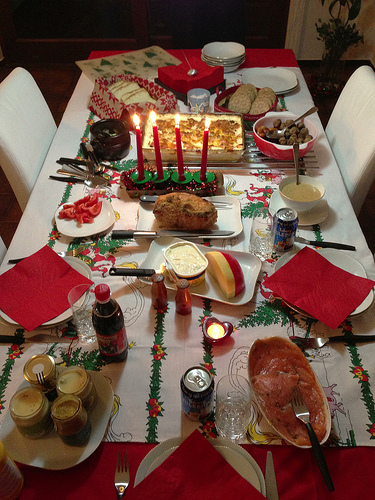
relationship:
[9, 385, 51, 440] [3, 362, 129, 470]
jar on plate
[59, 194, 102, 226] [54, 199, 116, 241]
tomatoes on a plate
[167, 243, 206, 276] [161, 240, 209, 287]
butter in tub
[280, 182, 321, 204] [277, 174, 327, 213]
soup in bowl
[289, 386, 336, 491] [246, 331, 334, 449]
fork in bowl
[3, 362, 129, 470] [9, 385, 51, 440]
plate holding jar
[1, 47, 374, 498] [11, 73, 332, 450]
table has meal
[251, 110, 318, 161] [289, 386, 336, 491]
bowl has a fork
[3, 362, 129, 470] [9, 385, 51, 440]
plate has jar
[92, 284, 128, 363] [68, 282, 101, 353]
bottle next to glass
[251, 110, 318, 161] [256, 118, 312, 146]
bowl has meatballs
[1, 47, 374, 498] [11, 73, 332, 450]
table has dinner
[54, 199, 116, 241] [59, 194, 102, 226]
plate has tomatoes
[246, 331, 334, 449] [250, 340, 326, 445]
plate has potatoes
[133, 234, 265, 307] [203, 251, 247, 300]
tray has cheese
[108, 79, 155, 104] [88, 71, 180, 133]
bread in containter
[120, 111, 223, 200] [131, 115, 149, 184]
center piece has candle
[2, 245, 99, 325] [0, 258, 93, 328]
napkin on plate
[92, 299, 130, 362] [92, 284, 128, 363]
soda in bottle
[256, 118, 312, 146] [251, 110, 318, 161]
meatballs in bowl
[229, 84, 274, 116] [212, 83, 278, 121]
cookies on plate